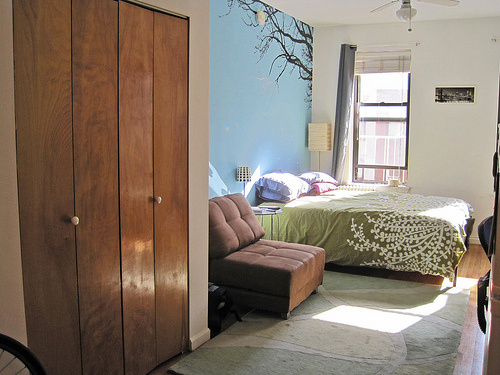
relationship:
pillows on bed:
[256, 171, 338, 202] [261, 168, 474, 278]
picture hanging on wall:
[431, 84, 475, 104] [303, 16, 499, 250]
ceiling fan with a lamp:
[365, 1, 465, 34] [394, 1, 420, 32]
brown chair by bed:
[210, 191, 330, 321] [250, 183, 476, 288]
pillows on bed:
[255, 143, 354, 205] [263, 158, 478, 285]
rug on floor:
[324, 281, 469, 370] [470, 252, 485, 275]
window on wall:
[351, 51, 408, 186] [303, 16, 499, 250]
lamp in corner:
[285, 113, 352, 177] [305, 22, 318, 118]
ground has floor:
[160, 225, 491, 371] [455, 236, 490, 290]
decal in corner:
[221, 0, 312, 109] [238, 0, 355, 182]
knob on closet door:
[146, 192, 167, 209] [18, 7, 216, 369]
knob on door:
[64, 209, 86, 230] [10, 0, 124, 373]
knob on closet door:
[155, 196, 162, 204] [14, 0, 190, 375]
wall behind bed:
[203, 1, 335, 255] [244, 152, 478, 296]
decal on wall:
[205, 0, 311, 202] [204, 1, 335, 220]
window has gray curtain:
[351, 52, 407, 185] [334, 40, 359, 184]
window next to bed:
[351, 52, 407, 185] [259, 147, 481, 279]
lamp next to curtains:
[308, 123, 331, 172] [332, 45, 354, 180]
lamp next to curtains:
[236, 167, 251, 194] [332, 45, 354, 180]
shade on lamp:
[306, 117, 339, 154] [287, 108, 362, 175]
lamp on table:
[232, 162, 251, 194] [235, 201, 285, 249]